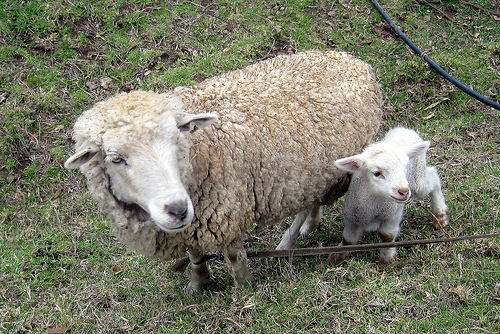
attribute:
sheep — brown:
[50, 34, 392, 299]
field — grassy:
[3, 4, 497, 331]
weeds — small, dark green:
[5, 4, 87, 75]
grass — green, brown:
[1, 5, 498, 332]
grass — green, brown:
[261, 282, 388, 332]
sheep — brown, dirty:
[19, 42, 409, 281]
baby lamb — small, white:
[328, 116, 450, 267]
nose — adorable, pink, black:
[157, 190, 204, 231]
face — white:
[95, 114, 210, 235]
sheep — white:
[322, 120, 463, 269]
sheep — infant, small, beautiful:
[330, 123, 449, 266]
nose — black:
[166, 195, 192, 221]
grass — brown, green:
[291, 271, 428, 331]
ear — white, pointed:
[333, 160, 360, 170]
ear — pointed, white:
[402, 140, 428, 160]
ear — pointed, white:
[173, 112, 215, 135]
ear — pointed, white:
[65, 140, 97, 167]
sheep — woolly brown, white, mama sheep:
[64, 49, 381, 298]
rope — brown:
[199, 182, 499, 310]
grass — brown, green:
[13, 254, 497, 333]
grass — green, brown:
[3, 2, 497, 83]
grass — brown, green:
[440, 84, 498, 241]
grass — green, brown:
[1, 81, 74, 275]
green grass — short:
[1, 10, 199, 58]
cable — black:
[365, 0, 499, 122]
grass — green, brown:
[87, 16, 189, 58]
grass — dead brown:
[29, 248, 194, 332]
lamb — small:
[337, 130, 451, 260]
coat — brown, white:
[204, 55, 338, 177]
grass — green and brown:
[438, 170, 497, 235]